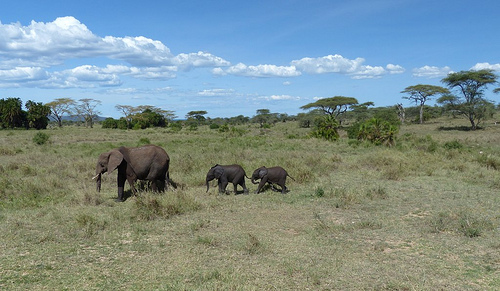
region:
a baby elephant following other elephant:
[248, 159, 307, 199]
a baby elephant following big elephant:
[202, 155, 253, 203]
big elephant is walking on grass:
[91, 137, 179, 210]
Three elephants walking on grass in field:
[78, 105, 306, 215]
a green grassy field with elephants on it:
[2, 112, 496, 288]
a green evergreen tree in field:
[446, 57, 493, 127]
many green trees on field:
[1, 65, 493, 142]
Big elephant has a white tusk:
[83, 142, 111, 202]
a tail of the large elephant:
[166, 157, 192, 195]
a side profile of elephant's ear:
[86, 141, 129, 208]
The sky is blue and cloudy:
[121, 18, 449, 92]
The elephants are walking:
[53, 134, 338, 223]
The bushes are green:
[292, 108, 428, 163]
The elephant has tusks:
[56, 146, 154, 213]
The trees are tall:
[381, 40, 498, 148]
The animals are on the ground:
[71, 175, 318, 221]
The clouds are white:
[33, 16, 261, 123]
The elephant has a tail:
[263, 150, 328, 237]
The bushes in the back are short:
[21, 70, 188, 145]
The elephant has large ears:
[82, 122, 149, 190]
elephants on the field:
[65, 126, 445, 286]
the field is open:
[148, 136, 386, 184]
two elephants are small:
[163, 137, 338, 224]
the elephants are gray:
[65, 134, 310, 229]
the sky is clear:
[42, 20, 363, 76]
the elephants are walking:
[80, 125, 385, 235]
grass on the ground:
[93, 187, 344, 254]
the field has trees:
[20, 75, 487, 190]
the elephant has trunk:
[47, 142, 225, 234]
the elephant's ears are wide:
[85, 165, 128, 205]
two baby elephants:
[204, 147, 299, 196]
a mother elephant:
[89, 141, 181, 205]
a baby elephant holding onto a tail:
[241, 169, 264, 185]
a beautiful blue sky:
[0, 3, 497, 125]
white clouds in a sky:
[2, 15, 499, 102]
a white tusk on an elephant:
[90, 166, 103, 184]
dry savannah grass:
[1, 150, 495, 284]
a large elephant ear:
[105, 147, 125, 177]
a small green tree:
[403, 76, 441, 127]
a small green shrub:
[30, 129, 50, 147]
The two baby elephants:
[202, 157, 298, 196]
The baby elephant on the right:
[248, 161, 295, 196]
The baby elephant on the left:
[202, 160, 254, 197]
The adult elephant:
[90, 141, 177, 202]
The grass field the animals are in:
[1, 115, 499, 290]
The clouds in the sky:
[0, 15, 496, 109]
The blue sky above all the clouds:
[0, 0, 496, 13]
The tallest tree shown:
[436, 61, 498, 141]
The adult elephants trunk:
[90, 160, 100, 190]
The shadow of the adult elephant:
[117, 177, 183, 200]